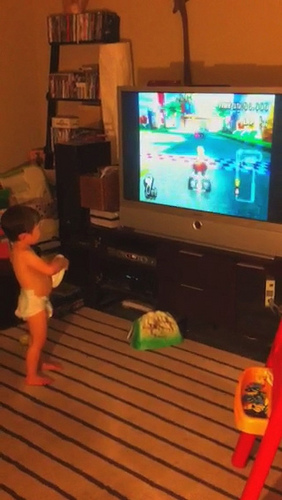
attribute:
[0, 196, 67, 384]
baby — playing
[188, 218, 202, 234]
object — round shaped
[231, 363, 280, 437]
tray — yellow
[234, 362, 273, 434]
tray — yellow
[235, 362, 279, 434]
tray — yellow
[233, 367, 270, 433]
tray — yellow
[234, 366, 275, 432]
tray — yellow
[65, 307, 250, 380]
stripe — black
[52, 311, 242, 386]
stripe — black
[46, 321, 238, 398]
stripe — black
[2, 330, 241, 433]
stripe — black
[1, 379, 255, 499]
stripe — black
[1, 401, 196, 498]
stripe — black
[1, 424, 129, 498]
sripe — black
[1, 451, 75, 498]
sripe — black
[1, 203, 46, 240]
hair — black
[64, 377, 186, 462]
stripes — brown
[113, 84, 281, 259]
television — showing video game